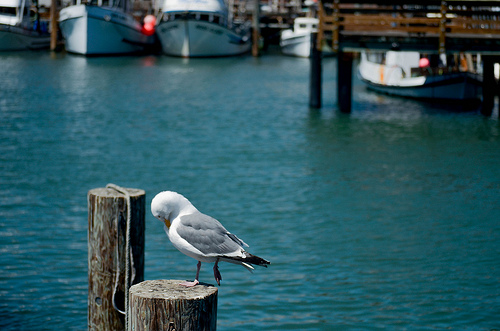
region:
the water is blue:
[86, 81, 461, 286]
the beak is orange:
[154, 207, 178, 232]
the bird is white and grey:
[139, 170, 264, 300]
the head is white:
[139, 182, 197, 222]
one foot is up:
[177, 255, 238, 310]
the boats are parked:
[11, 0, 263, 80]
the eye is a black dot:
[144, 209, 170, 224]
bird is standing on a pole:
[105, 186, 255, 318]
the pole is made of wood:
[111, 255, 225, 324]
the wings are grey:
[167, 195, 249, 260]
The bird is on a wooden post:
[136, 177, 202, 327]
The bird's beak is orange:
[151, 210, 181, 230]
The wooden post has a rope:
[89, 165, 149, 321]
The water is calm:
[296, 155, 403, 273]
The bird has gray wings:
[171, 210, 287, 294]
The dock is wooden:
[306, 21, 457, 142]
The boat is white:
[51, 5, 143, 75]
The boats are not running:
[153, 12, 365, 96]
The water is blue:
[214, 120, 345, 201]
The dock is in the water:
[295, 77, 498, 165]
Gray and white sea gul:
[148, 190, 273, 285]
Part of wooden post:
[85, 184, 147, 279]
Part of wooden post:
[127, 280, 222, 325]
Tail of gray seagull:
[247, 251, 277, 273]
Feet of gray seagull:
[182, 265, 227, 292]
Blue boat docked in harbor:
[57, 5, 131, 51]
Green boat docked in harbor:
[150, 3, 250, 59]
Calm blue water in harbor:
[236, 166, 371, 235]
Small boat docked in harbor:
[271, 14, 317, 63]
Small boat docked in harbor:
[356, 52, 483, 102]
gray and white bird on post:
[142, 184, 251, 271]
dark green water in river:
[28, 68, 100, 123]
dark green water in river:
[22, 148, 73, 210]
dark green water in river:
[27, 209, 84, 281]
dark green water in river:
[274, 244, 344, 297]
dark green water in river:
[336, 219, 437, 287]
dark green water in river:
[339, 155, 424, 216]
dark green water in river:
[63, 87, 130, 132]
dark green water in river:
[166, 92, 215, 133]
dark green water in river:
[242, 107, 304, 192]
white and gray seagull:
[153, 181, 241, 288]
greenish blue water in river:
[18, 69, 96, 126]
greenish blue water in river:
[25, 103, 87, 163]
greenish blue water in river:
[2, 172, 70, 236]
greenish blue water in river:
[88, 66, 189, 144]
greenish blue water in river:
[198, 78, 276, 132]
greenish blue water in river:
[225, 121, 302, 186]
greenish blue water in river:
[356, 133, 433, 198]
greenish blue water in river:
[412, 155, 469, 222]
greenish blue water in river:
[262, 186, 367, 243]